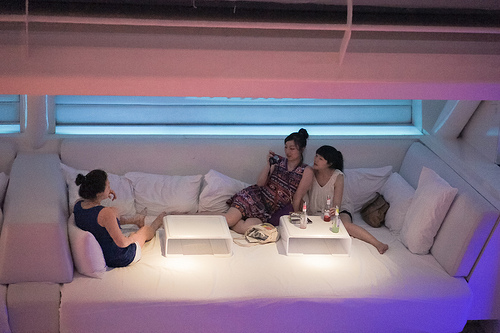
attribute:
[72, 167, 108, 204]
hair — black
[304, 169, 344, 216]
dress — white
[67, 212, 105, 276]
pillow — white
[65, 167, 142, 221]
pillow — white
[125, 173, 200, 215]
pillow — white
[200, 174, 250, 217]
pillow — white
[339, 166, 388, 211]
pillow — white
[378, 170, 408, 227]
pillow — white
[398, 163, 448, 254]
pillow — white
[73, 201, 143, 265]
dress — blue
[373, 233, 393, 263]
foot — bare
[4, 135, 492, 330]
couch — large, white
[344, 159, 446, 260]
pillows — white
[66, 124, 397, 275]
women — three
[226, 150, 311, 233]
dress — sleeveless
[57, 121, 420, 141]
reflection — light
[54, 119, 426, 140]
sill — window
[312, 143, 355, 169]
hair — black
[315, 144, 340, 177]
head — woman's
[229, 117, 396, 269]
women — 2, sitting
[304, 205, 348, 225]
skirt — white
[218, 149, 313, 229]
dress — multiprint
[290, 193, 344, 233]
bottles — three, group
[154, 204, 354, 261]
trays — square, white, 2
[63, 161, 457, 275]
pillows — white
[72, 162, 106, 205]
hair — dark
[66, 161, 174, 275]
woman — sitting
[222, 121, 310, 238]
woman — sitting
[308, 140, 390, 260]
woman — sitting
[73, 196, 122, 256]
shirt — blue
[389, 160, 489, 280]
pillows — white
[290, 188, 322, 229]
bottle — clear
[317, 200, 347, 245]
bottle — clear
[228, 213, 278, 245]
bag — white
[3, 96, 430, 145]
window — long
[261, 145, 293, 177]
camera — silver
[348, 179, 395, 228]
purse — tan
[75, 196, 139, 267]
dress — sleeveless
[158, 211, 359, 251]
trays — small, white